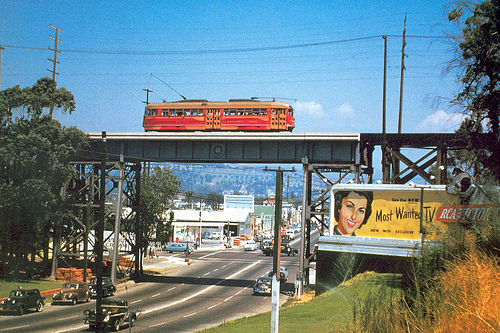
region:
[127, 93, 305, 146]
Red train on a bridge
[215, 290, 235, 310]
White lane lines on a road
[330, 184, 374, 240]
Picture of woman on billboard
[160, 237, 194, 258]
Blue card on road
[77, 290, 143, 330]
Old truck driving down road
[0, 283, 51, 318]
Old car parked on side of road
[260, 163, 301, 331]
Wooden telephone pole on greass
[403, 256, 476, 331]
Tall brown grass in field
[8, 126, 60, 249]
green tree next to a bridge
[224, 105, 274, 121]
People riding on a red train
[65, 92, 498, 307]
Overpass for public transit trains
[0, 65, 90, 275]
Large green trees in grassy area in front of the overpass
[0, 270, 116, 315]
Three cars on the left side of the road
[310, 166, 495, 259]
Yellow billboard on the right side of the road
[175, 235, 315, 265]
Four way intersection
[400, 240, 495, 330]
Orange foliage in front of the billboard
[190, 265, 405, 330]
Grassy area in front of the billboard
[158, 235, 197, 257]
Blue car in the four way intersection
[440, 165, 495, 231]
Dog on the yellow billboard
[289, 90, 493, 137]
White puffy clouds in the sky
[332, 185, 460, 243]
A television billboard advertisement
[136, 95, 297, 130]
A public transport train system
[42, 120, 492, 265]
An overhanging public train railway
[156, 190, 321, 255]
A public area of shops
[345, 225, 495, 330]
Foliage in the foreground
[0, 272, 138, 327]
Old vehicles on a busy highway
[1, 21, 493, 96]
Telephone wires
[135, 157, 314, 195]
City countryside in the background.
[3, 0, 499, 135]
A blue sky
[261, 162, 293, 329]
Telephone pole in the foreground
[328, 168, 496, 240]
billboard for RCA Victor TV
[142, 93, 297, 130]
trolley car on over pass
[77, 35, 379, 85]
electric trolley car wires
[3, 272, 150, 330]
old cars on the road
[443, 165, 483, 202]
the RCA puppies head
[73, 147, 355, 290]
iron beams holding up bridge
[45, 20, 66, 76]
top of electric pole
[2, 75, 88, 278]
trees on left of photo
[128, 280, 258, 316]
four lane highway, no turning lane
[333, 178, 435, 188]
three of the lights on the billboard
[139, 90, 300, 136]
trolley car on the bridge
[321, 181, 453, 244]
advertisement on a billboard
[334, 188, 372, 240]
smiling woman on the billboard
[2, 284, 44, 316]
black car on the road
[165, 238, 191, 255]
blue car on the road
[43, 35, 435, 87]
telephone pole and telephone lines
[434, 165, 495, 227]
RCA advertisement billboard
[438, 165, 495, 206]
black and white dog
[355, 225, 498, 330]
weeds on the side of the road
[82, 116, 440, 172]
bridge over the road